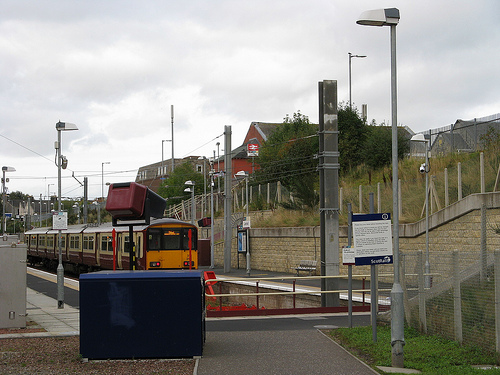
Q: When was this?
A: Daytime.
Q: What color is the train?
A: Yellow.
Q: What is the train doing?
A: Moving.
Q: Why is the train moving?
A: To reach its destination.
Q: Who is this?
A: No one.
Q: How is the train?
A: In motion.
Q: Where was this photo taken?
A: At a train stop.